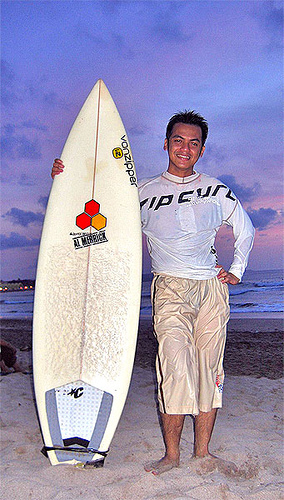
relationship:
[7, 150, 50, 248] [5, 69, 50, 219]
clouds in sky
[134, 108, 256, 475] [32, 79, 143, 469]
man holding board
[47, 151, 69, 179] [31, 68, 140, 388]
fingers holding surfboard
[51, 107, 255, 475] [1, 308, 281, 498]
man bare feet in sand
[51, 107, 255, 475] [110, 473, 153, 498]
man by beach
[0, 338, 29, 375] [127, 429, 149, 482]
person sitting on sand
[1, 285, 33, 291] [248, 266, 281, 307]
lights on ocean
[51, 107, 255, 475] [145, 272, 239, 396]
man wearing shorts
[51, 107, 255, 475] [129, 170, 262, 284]
man wearing shirt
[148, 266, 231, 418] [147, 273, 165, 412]
shorts with stripe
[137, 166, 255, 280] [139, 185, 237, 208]
shirt with text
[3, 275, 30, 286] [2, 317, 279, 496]
homes on beach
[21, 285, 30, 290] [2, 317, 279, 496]
buildings on beach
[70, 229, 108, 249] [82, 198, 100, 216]
text with hexagon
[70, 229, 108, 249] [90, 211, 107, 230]
text with hexagon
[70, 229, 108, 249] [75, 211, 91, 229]
text with hexagon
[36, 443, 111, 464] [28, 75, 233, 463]
ankle strap wrapped around surfboard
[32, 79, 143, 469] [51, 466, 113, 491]
board stuck in sand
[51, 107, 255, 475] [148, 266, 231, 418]
man wearing shorts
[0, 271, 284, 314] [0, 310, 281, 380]
wave crashing on shore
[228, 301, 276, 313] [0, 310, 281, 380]
wave crashing on shore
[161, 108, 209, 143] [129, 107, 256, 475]
brown hair on young man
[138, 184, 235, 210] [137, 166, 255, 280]
logo on shirt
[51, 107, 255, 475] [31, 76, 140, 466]
man holding board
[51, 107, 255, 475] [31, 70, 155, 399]
man holding surfboard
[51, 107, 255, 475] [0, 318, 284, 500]
man standing on beach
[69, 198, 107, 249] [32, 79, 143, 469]
logo on a board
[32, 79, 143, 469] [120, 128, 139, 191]
board says von zipper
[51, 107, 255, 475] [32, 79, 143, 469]
man posing with board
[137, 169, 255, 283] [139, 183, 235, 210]
shirt with black lettering